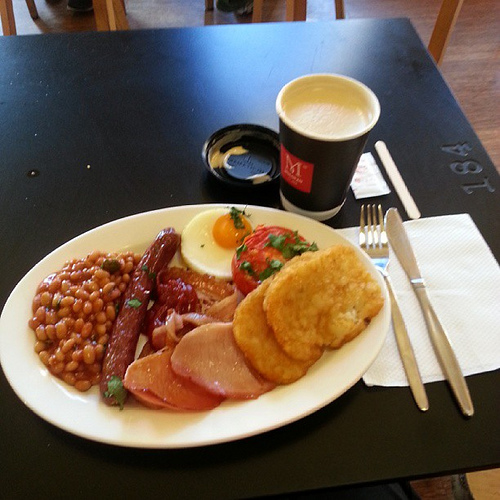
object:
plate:
[0, 204, 392, 453]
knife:
[385, 201, 474, 411]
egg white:
[180, 205, 234, 276]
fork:
[355, 199, 431, 413]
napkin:
[329, 211, 499, 389]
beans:
[27, 248, 144, 395]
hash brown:
[261, 242, 384, 362]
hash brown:
[234, 281, 308, 384]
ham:
[168, 318, 272, 398]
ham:
[125, 347, 222, 410]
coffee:
[284, 81, 373, 137]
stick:
[373, 139, 423, 224]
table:
[0, 11, 499, 498]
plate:
[19, 152, 409, 464]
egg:
[177, 202, 263, 281]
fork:
[357, 203, 432, 415]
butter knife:
[383, 204, 474, 418]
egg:
[180, 206, 252, 278]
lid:
[201, 119, 283, 191]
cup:
[271, 68, 380, 223]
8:
[450, 156, 482, 176]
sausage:
[100, 227, 177, 406]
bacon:
[149, 264, 236, 333]